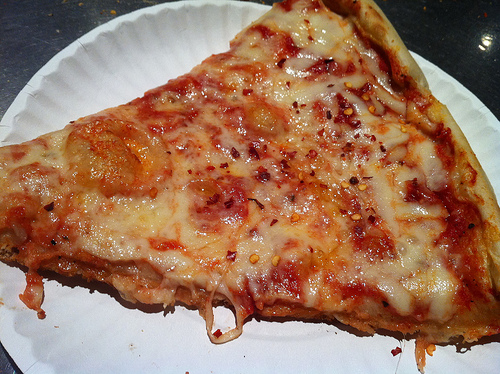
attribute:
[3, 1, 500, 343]
pizza — sliced, cut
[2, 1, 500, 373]
plate — white, round, serrated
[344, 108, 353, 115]
spices — scattered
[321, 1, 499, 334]
crust — well done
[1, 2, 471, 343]
cheese — melted, hanging, thick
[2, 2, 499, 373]
surface — grey, black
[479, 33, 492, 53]
light — on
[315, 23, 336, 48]
spot — white